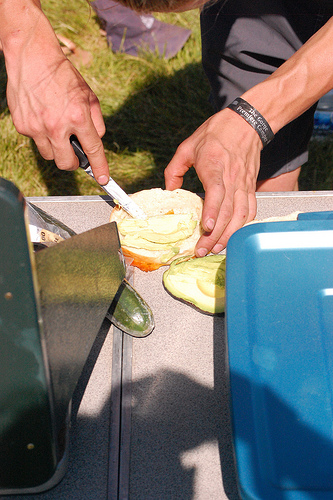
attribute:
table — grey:
[31, 189, 332, 498]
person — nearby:
[0, 1, 332, 258]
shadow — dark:
[71, 362, 222, 489]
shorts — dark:
[196, 4, 324, 176]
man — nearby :
[6, 0, 329, 254]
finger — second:
[190, 230, 217, 261]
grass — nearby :
[0, 0, 332, 193]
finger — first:
[196, 168, 225, 232]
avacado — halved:
[161, 254, 226, 313]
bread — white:
[100, 166, 224, 275]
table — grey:
[0, 184, 328, 499]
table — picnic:
[170, 320, 206, 339]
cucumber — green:
[103, 280, 155, 338]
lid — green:
[0, 177, 94, 483]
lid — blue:
[221, 216, 331, 408]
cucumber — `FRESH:
[98, 275, 163, 349]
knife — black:
[67, 129, 136, 213]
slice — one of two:
[117, 192, 201, 235]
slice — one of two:
[126, 244, 190, 270]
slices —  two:
[113, 187, 199, 269]